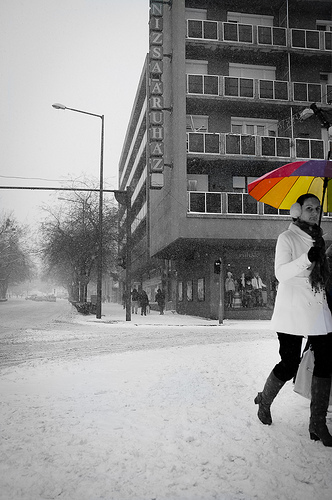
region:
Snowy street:
[3, 210, 260, 498]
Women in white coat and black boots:
[246, 180, 330, 456]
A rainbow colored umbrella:
[244, 144, 330, 230]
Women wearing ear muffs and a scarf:
[274, 189, 330, 303]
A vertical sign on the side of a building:
[136, 0, 180, 203]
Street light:
[39, 93, 111, 324]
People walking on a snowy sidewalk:
[91, 268, 183, 328]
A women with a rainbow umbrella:
[220, 143, 330, 441]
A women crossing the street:
[225, 185, 330, 449]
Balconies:
[186, 3, 330, 154]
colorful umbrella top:
[244, 155, 327, 206]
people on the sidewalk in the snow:
[125, 284, 169, 315]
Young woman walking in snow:
[250, 191, 329, 449]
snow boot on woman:
[249, 367, 286, 426]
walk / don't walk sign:
[208, 254, 222, 273]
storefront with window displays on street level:
[173, 245, 270, 317]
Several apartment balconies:
[183, 0, 329, 160]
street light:
[48, 100, 66, 108]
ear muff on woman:
[287, 201, 299, 216]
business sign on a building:
[146, 0, 170, 189]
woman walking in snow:
[210, 143, 329, 449]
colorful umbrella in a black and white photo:
[196, 130, 326, 204]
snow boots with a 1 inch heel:
[240, 361, 326, 454]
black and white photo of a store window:
[219, 235, 265, 320]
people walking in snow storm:
[125, 283, 168, 324]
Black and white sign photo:
[130, 0, 174, 200]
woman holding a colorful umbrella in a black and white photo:
[137, 96, 329, 472]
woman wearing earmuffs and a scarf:
[279, 192, 327, 233]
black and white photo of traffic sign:
[205, 254, 223, 322]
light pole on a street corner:
[49, 99, 103, 317]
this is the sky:
[13, 9, 90, 65]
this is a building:
[160, 4, 244, 226]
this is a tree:
[53, 206, 92, 282]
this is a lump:
[50, 101, 69, 111]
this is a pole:
[98, 119, 105, 180]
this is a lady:
[276, 196, 326, 414]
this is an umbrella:
[248, 163, 322, 185]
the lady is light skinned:
[302, 210, 306, 216]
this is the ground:
[92, 363, 216, 454]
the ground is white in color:
[117, 378, 194, 409]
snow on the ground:
[13, 343, 254, 432]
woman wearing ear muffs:
[287, 195, 322, 223]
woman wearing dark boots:
[241, 373, 328, 453]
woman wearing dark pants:
[264, 331, 331, 400]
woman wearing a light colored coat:
[265, 221, 330, 338]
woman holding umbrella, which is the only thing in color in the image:
[243, 153, 329, 259]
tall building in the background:
[116, 0, 330, 328]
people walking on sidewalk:
[102, 263, 183, 329]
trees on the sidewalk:
[42, 176, 119, 318]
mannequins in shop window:
[210, 248, 272, 322]